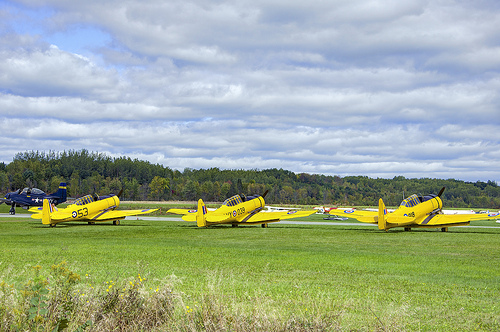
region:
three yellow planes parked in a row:
[22, 177, 496, 236]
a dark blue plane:
[2, 179, 77, 221]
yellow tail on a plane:
[374, 194, 391, 236]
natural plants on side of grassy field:
[11, 259, 318, 329]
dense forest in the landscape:
[17, 139, 497, 203]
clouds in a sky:
[160, 92, 432, 158]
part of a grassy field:
[277, 233, 399, 287]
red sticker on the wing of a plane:
[312, 200, 337, 217]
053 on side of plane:
[67, 206, 96, 221]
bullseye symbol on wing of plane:
[184, 201, 197, 216]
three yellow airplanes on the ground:
[16, 188, 498, 240]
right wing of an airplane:
[416, 205, 497, 232]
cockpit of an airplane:
[220, 185, 255, 205]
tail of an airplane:
[181, 196, 231, 226]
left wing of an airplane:
[312, 201, 372, 225]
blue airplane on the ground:
[1, 180, 71, 220]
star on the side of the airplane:
[30, 195, 45, 206]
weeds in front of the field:
[7, 250, 421, 330]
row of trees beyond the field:
[0, 148, 498, 205]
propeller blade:
[430, 182, 449, 199]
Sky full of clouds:
[3, 5, 498, 180]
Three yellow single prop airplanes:
[28, 183, 498, 248]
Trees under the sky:
[4, 142, 495, 211]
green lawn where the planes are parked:
[5, 215, 496, 290]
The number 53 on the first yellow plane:
[67, 203, 96, 223]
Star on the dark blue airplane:
[24, 195, 52, 209]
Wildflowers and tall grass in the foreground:
[14, 253, 484, 328]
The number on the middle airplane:
[229, 204, 261, 219]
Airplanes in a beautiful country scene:
[3, 4, 497, 329]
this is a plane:
[320, 170, 491, 255]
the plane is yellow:
[328, 174, 484, 254]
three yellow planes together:
[28, 170, 493, 270]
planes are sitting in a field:
[32, 158, 484, 330]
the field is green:
[53, 217, 481, 327]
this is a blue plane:
[8, 168, 80, 223]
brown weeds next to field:
[62, 259, 366, 328]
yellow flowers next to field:
[20, 242, 85, 314]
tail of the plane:
[363, 191, 395, 230]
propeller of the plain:
[251, 179, 276, 208]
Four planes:
[8, 163, 488, 246]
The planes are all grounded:
[0, 163, 490, 231]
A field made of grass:
[15, 225, 486, 307]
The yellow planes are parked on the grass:
[19, 183, 472, 242]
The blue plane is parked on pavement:
[1, 178, 81, 210]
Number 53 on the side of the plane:
[58, 198, 105, 224]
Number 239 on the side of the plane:
[222, 196, 254, 222]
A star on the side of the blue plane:
[25, 191, 48, 205]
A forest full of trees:
[24, 148, 489, 216]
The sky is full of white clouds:
[6, 50, 486, 170]